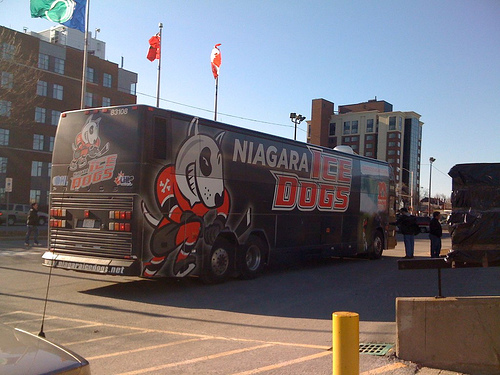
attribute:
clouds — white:
[261, 38, 374, 93]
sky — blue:
[247, 41, 347, 102]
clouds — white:
[242, 31, 375, 79]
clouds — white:
[281, 23, 387, 83]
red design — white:
[210, 42, 222, 76]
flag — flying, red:
[146, 21, 166, 106]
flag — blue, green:
[30, 0, 90, 29]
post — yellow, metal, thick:
[332, 309, 361, 375]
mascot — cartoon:
[140, 117, 231, 277]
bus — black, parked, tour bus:
[42, 109, 395, 281]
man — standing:
[398, 206, 422, 261]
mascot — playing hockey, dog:
[140, 118, 252, 280]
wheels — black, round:
[207, 236, 236, 285]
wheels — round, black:
[367, 227, 385, 259]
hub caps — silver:
[372, 236, 383, 253]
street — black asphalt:
[89, 280, 333, 372]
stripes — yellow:
[103, 331, 331, 374]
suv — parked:
[1, 200, 29, 228]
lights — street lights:
[291, 109, 304, 140]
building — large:
[0, 26, 49, 205]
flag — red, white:
[209, 41, 222, 120]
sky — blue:
[222, 2, 499, 95]